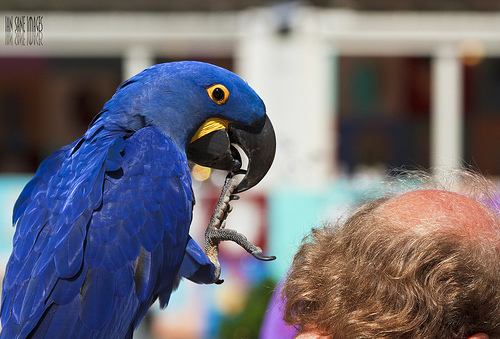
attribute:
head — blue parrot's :
[124, 53, 308, 205]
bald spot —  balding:
[355, 171, 497, 294]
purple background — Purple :
[260, 279, 295, 336]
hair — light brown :
[290, 185, 489, 337]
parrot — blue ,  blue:
[7, 57, 279, 334]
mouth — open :
[191, 123, 253, 175]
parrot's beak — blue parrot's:
[185, 112, 275, 193]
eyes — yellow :
[209, 87, 231, 103]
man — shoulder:
[281, 160, 497, 337]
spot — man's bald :
[376, 183, 498, 254]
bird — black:
[0, 53, 278, 335]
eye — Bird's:
[203, 77, 228, 110]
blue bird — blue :
[1, 56, 280, 337]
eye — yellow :
[212, 79, 229, 100]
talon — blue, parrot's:
[249, 244, 286, 269]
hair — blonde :
[288, 202, 499, 337]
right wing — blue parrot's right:
[72, 131, 196, 337]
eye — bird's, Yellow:
[193, 70, 237, 115]